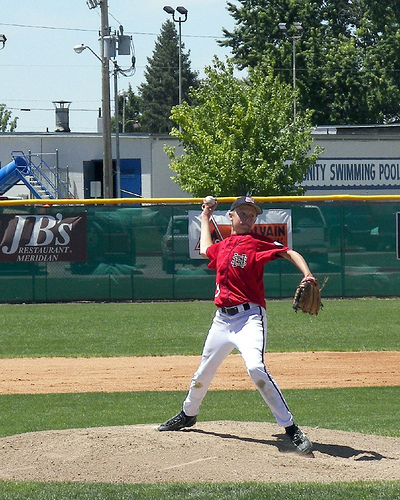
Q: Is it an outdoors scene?
A: Yes, it is outdoors.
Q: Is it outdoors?
A: Yes, it is outdoors.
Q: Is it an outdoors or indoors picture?
A: It is outdoors.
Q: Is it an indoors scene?
A: No, it is outdoors.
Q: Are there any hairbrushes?
A: No, there are no hairbrushes.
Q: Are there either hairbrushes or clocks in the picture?
A: No, there are no hairbrushes or clocks.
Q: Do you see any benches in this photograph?
A: No, there are no benches.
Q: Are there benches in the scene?
A: No, there are no benches.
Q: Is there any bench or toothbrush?
A: No, there are no benches or toothbrushes.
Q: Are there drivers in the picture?
A: No, there are no drivers.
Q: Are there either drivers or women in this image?
A: No, there are no drivers or women.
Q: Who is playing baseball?
A: The boy is playing baseball.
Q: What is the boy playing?
A: The boy is playing baseball.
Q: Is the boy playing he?
A: Yes, the boy is playing baseball.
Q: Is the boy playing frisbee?
A: No, the boy is playing baseball.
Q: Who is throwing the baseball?
A: The boy is throwing the baseball.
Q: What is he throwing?
A: The boy is throwing the baseball.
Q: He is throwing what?
A: The boy is throwing the baseball.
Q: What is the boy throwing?
A: The boy is throwing the baseball.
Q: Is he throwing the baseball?
A: Yes, the boy is throwing the baseball.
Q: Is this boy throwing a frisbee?
A: No, the boy is throwing the baseball.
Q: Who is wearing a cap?
A: The boy is wearing a cap.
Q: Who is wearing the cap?
A: The boy is wearing a cap.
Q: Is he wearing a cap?
A: Yes, the boy is wearing a cap.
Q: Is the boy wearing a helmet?
A: No, the boy is wearing a cap.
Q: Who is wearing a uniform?
A: The boy is wearing a uniform.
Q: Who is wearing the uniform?
A: The boy is wearing a uniform.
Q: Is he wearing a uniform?
A: Yes, the boy is wearing a uniform.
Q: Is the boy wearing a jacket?
A: No, the boy is wearing a uniform.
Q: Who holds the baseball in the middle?
A: The boy holds the baseball.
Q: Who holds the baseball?
A: The boy holds the baseball.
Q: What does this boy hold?
A: The boy holds the baseball.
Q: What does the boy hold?
A: The boy holds the baseball.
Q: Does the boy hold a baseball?
A: Yes, the boy holds a baseball.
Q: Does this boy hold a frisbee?
A: No, the boy holds a baseball.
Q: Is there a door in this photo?
A: Yes, there is a door.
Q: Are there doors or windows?
A: Yes, there is a door.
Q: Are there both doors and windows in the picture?
A: No, there is a door but no windows.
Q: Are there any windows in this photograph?
A: No, there are no windows.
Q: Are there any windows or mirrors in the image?
A: No, there are no windows or mirrors.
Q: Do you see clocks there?
A: No, there are no clocks.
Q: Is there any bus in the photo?
A: No, there are no buses.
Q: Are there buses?
A: No, there are no buses.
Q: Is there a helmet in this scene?
A: No, there are no helmets.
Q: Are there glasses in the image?
A: No, there are no glasses.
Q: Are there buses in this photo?
A: No, there are no buses.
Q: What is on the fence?
A: The sign is on the fence.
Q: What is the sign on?
A: The sign is on the fence.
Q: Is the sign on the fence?
A: Yes, the sign is on the fence.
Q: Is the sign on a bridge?
A: No, the sign is on the fence.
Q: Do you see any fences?
A: Yes, there is a fence.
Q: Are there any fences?
A: Yes, there is a fence.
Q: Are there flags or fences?
A: Yes, there is a fence.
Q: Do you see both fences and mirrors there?
A: No, there is a fence but no mirrors.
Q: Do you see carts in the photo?
A: No, there are no carts.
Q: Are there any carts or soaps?
A: No, there are no carts or soaps.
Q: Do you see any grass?
A: Yes, there is grass.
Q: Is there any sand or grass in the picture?
A: Yes, there is grass.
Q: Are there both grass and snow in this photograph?
A: No, there is grass but no snow.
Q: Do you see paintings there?
A: No, there are no paintings.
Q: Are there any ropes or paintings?
A: No, there are no paintings or ropes.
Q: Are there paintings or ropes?
A: No, there are no paintings or ropes.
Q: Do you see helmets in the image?
A: No, there are no helmets.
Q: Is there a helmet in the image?
A: No, there are no helmets.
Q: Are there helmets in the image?
A: No, there are no helmets.